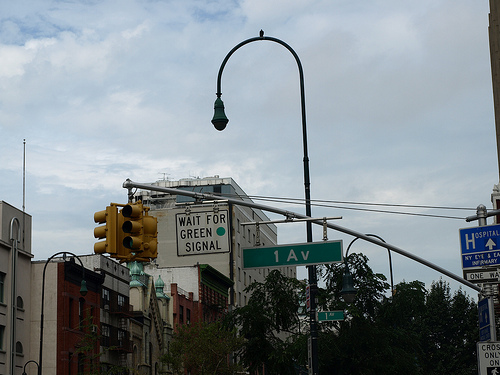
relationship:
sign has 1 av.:
[241, 240, 346, 268] [272, 247, 312, 264]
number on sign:
[272, 247, 312, 264] [241, 240, 346, 268]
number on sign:
[321, 310, 339, 321] [312, 309, 351, 320]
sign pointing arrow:
[456, 224, 500, 270] [482, 237, 497, 252]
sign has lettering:
[176, 212, 233, 258] [179, 213, 228, 250]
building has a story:
[34, 252, 112, 372] [55, 349, 101, 374]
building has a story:
[34, 252, 112, 372] [57, 289, 101, 340]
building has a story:
[34, 252, 112, 372] [36, 261, 103, 296]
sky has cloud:
[2, 0, 498, 297] [6, 32, 146, 90]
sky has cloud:
[2, 0, 498, 297] [43, 150, 278, 192]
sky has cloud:
[2, 0, 498, 297] [344, 171, 464, 227]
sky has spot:
[2, 0, 498, 297] [5, 16, 34, 30]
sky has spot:
[2, 0, 498, 297] [34, 25, 64, 41]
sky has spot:
[2, 0, 498, 297] [10, 37, 31, 46]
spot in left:
[5, 16, 34, 30] [0, 2, 117, 65]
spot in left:
[34, 25, 64, 41] [0, 2, 117, 65]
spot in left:
[10, 37, 31, 46] [0, 2, 117, 65]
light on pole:
[207, 96, 231, 129] [208, 28, 331, 373]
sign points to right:
[461, 266, 500, 286] [467, 270, 500, 282]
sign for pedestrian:
[474, 342, 499, 373] [487, 365, 500, 373]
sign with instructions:
[474, 342, 499, 373] [481, 342, 500, 366]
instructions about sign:
[481, 342, 500, 366] [474, 342, 499, 373]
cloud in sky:
[6, 32, 146, 90] [2, 0, 498, 297]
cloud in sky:
[43, 150, 278, 192] [2, 0, 498, 297]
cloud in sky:
[344, 171, 464, 227] [2, 0, 498, 297]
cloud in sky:
[244, 2, 499, 56] [2, 0, 498, 297]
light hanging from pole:
[120, 200, 146, 263] [123, 175, 485, 299]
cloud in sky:
[138, 2, 259, 34] [2, 0, 498, 297]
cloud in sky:
[153, 68, 300, 116] [2, 0, 498, 297]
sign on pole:
[241, 240, 346, 268] [208, 28, 331, 373]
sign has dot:
[176, 212, 233, 258] [214, 225, 227, 237]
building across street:
[34, 252, 112, 372] [472, 5, 500, 371]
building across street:
[2, 198, 38, 373] [472, 5, 500, 371]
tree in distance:
[461, 297, 479, 374] [247, 277, 482, 373]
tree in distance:
[421, 280, 457, 369] [247, 277, 482, 373]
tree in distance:
[335, 256, 392, 374] [247, 277, 482, 373]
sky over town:
[2, 0, 498, 297] [2, 0, 498, 372]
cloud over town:
[6, 32, 146, 90] [2, 0, 498, 372]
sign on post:
[456, 224, 500, 270] [452, 200, 499, 338]